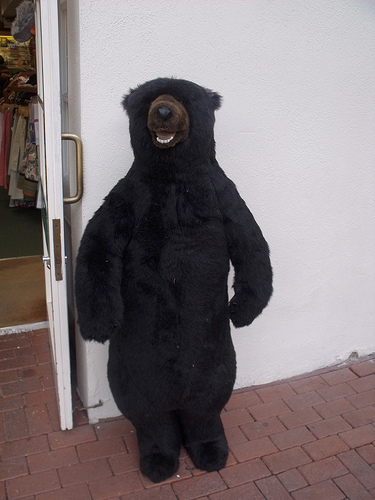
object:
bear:
[72, 78, 272, 482]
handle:
[59, 132, 81, 204]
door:
[31, 0, 75, 430]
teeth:
[160, 140, 163, 143]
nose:
[156, 103, 175, 120]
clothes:
[9, 113, 24, 203]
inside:
[3, 1, 54, 323]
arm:
[74, 191, 128, 342]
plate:
[52, 218, 63, 281]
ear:
[204, 87, 223, 110]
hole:
[348, 350, 359, 360]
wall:
[86, 0, 370, 418]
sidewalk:
[32, 388, 375, 500]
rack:
[0, 65, 34, 79]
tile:
[262, 445, 312, 475]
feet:
[184, 432, 229, 471]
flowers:
[31, 169, 37, 178]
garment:
[31, 103, 49, 204]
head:
[120, 76, 223, 166]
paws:
[228, 292, 254, 328]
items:
[10, 0, 37, 35]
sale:
[3, 11, 71, 390]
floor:
[0, 253, 54, 329]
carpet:
[0, 208, 42, 256]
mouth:
[151, 120, 184, 147]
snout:
[144, 97, 188, 145]